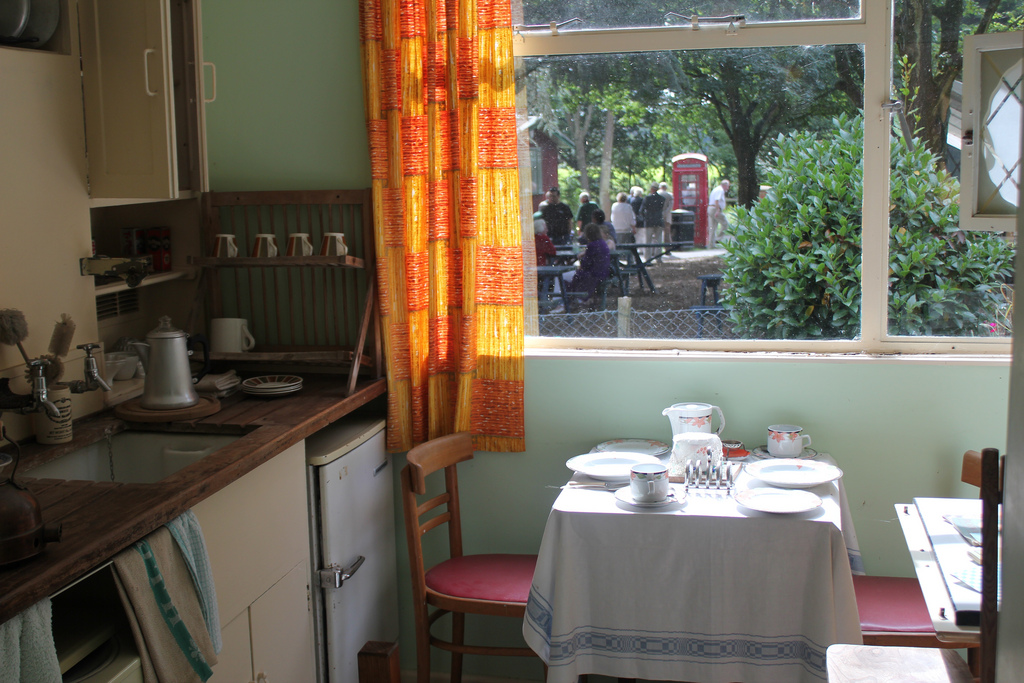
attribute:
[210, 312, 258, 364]
cup — white , large 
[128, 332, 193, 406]
cup — silver 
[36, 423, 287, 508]
sink — small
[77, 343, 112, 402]
faucet — silver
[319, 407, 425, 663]
fridge — small , white 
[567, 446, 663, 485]
plate — white 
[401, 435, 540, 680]
chair — small 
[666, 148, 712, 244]
booth — red 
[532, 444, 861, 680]
tablecloth — white 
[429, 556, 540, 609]
seat — red 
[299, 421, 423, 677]
refrigerator — white , Small 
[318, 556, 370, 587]
handle — Silver 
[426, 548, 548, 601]
seat — red 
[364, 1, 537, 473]
curtain — Orange and yellow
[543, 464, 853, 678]
tablecloth — white 